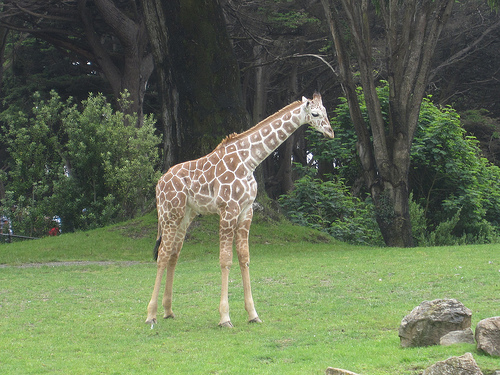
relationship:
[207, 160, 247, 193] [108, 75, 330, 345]
spot on giraffe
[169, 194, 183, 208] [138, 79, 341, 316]
spot on giraffe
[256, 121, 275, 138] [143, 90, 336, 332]
spot on a giraffe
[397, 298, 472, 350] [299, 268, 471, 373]
rock on ground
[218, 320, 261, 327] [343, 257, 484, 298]
hooves on grass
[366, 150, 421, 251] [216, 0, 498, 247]
bark on a tree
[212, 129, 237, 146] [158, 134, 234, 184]
brown mane on a back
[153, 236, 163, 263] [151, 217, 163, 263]
hair on a giraffe's tail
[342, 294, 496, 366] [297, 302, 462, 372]
rocks on ground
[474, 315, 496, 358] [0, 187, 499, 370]
rock on ground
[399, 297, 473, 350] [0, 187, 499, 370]
rock on ground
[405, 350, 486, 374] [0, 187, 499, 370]
rock on ground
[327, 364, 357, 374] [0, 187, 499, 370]
rock on ground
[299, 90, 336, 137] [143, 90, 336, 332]
head of giraffe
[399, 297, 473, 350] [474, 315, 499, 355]
rock near rock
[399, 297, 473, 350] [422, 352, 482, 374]
rock near rock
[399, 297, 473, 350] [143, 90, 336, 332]
rock near giraffe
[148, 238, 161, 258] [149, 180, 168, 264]
hair at end of giraffe's tail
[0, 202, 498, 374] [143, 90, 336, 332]
grass all around giraffe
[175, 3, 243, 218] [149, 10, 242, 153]
moss on tree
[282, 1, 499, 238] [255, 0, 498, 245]
grouping of trees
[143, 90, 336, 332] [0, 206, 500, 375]
giraffe on grass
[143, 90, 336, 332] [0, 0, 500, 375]
giraffe in zoo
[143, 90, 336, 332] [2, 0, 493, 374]
giraffe in zoo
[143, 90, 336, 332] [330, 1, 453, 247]
giraffe near tree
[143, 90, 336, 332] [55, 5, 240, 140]
giraffe near tree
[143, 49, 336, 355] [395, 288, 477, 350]
giraffe near rock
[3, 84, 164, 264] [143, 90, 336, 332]
bush near giraffe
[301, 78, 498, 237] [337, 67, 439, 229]
bush behind tree